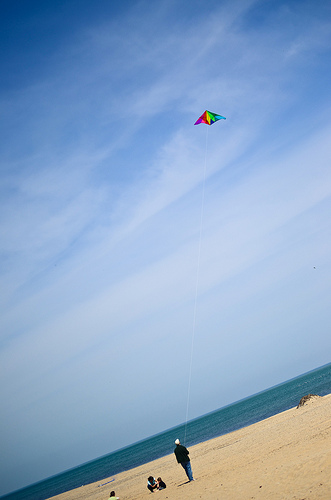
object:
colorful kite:
[193, 109, 226, 126]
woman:
[148, 475, 159, 493]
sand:
[39, 488, 103, 497]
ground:
[236, 426, 331, 500]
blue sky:
[2, 1, 329, 498]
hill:
[297, 393, 325, 410]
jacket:
[174, 444, 191, 463]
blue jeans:
[181, 463, 193, 481]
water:
[0, 447, 123, 500]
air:
[104, 0, 331, 320]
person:
[106, 491, 121, 499]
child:
[157, 477, 166, 491]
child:
[147, 475, 157, 492]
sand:
[249, 456, 325, 497]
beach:
[3, 474, 117, 499]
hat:
[175, 439, 180, 445]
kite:
[110, 491, 115, 497]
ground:
[119, 487, 153, 498]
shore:
[203, 396, 331, 460]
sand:
[265, 391, 319, 438]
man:
[174, 438, 195, 481]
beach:
[255, 444, 301, 479]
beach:
[143, 438, 221, 496]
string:
[197, 154, 206, 291]